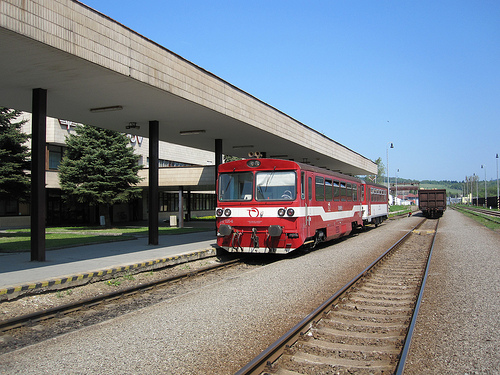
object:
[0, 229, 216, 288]
passenger walkway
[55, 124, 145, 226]
tree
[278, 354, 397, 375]
gravel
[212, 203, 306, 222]
line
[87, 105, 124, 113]
lights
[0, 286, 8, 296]
stripes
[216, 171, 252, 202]
window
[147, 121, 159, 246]
post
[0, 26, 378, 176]
ceiling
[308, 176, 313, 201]
windows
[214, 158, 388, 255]
train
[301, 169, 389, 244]
side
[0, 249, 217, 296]
caution tape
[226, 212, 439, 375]
train tracks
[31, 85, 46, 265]
post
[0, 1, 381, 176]
overhang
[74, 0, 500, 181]
sky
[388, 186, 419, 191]
roof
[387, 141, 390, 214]
pole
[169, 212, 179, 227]
bin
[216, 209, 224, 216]
lights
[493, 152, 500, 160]
lights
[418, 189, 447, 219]
train car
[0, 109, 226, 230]
building